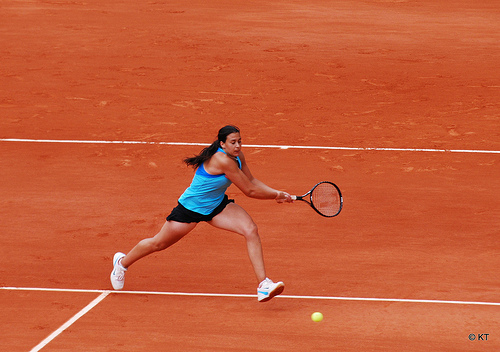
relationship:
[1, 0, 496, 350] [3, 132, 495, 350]
tennis court marked white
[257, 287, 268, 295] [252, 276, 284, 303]
design in shoe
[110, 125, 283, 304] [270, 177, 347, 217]
woman swinging tennis rakett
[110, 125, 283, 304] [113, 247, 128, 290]
woman wearing shoes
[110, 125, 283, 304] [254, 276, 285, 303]
woman wearing shoe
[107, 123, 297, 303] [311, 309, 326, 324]
woman about to hit tennis ball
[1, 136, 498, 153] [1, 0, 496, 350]
line on tennis court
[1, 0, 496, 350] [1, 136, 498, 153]
tennis court has a line